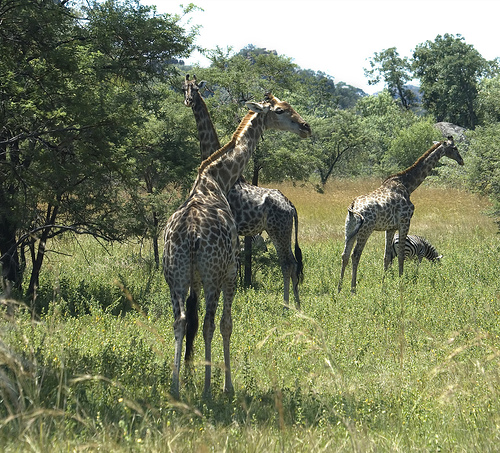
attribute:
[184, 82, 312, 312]
giraffe — spooted, tan, brown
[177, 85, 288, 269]
giraffe — Tall 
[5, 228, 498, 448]
grass — tall, green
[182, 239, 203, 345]
tail — Long 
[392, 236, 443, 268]
zebra — lone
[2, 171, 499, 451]
grass — Green 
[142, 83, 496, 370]
giraffe — Tall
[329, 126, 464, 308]
giraffe — Tall 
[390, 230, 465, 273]
zebra — Short 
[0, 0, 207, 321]
tree — tall, scrubby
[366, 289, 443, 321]
green grass — Green 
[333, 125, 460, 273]
giraffe — Tall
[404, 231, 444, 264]
zebra — black, white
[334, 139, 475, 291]
giraffe — Tall 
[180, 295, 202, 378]
black tail — long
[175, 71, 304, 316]
giraffe — Tan , Brown 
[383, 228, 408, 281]
legs — Long 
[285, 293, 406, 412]
grass — Green 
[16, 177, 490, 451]
treegrass — Green , Yellow 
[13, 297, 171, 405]
grass — short, brown, green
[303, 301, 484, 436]
grass — tall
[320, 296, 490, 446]
grass — green, short, yellow, brown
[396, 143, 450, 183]
mane — brown